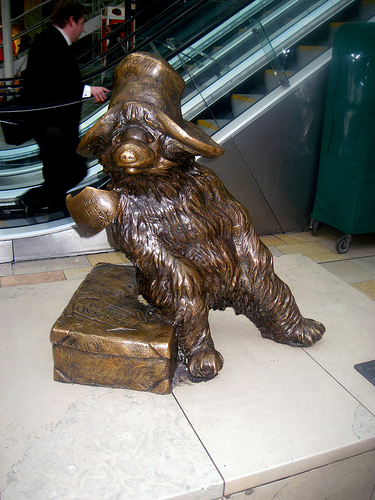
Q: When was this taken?
A: During the day.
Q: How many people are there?
A: One.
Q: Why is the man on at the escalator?
A: To get to the next floor.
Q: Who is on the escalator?
A: A man in a suit.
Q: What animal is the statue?
A: Bear.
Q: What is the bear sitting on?
A: Box.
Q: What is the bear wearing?
A: Hat.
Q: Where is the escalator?
A: Behind the statue.